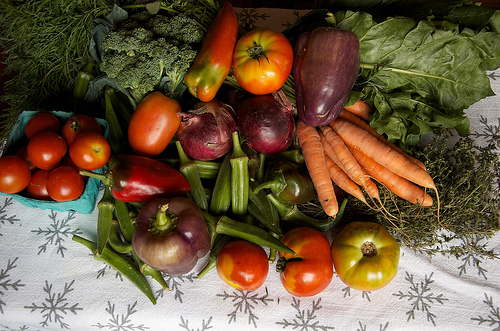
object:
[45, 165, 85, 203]
tomatoe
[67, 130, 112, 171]
tomatoe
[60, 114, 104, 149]
tomatoe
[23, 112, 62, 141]
tomatoe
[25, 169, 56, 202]
tomatoe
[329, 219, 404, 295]
tomatoe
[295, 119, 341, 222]
carrot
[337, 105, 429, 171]
carrot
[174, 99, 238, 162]
onion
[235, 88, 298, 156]
onion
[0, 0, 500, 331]
table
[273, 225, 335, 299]
tomatoe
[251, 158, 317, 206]
pepper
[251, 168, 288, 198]
stem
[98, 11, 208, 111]
broccoli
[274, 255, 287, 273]
stem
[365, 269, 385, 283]
light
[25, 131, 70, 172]
tomatoes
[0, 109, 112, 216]
carton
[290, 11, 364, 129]
pepper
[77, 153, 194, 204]
pepper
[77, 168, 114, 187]
end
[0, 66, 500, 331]
tablecloth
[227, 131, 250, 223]
okra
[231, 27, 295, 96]
tomatoe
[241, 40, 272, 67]
stalk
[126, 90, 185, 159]
tomatoe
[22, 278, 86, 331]
snowflake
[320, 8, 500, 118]
spinach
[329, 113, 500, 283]
parsley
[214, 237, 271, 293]
tomatoe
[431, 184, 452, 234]
root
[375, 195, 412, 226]
root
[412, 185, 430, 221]
root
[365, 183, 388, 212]
root